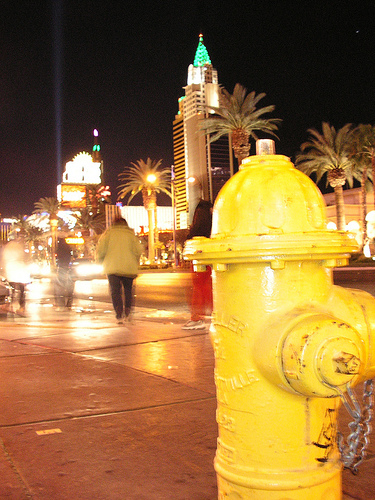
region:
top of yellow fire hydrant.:
[249, 180, 292, 219]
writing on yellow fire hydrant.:
[218, 369, 251, 456]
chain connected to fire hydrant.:
[345, 399, 366, 461]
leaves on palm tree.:
[220, 98, 273, 129]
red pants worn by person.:
[192, 282, 208, 315]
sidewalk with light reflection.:
[40, 318, 123, 396]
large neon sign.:
[68, 147, 101, 181]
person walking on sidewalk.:
[99, 216, 136, 309]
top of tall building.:
[189, 40, 213, 65]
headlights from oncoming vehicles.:
[78, 266, 101, 278]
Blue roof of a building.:
[168, 20, 223, 84]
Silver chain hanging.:
[314, 368, 373, 490]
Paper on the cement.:
[0, 371, 89, 478]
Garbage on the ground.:
[145, 348, 192, 399]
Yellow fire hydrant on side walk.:
[187, 155, 337, 493]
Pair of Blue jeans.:
[87, 272, 151, 353]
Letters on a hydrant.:
[190, 300, 247, 477]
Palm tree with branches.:
[113, 136, 193, 299]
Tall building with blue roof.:
[133, 15, 253, 263]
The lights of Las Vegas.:
[20, 111, 120, 218]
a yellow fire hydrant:
[182, 136, 362, 395]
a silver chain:
[323, 354, 370, 486]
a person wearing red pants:
[164, 183, 232, 325]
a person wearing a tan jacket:
[92, 216, 139, 289]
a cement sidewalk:
[0, 354, 212, 467]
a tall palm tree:
[114, 152, 180, 255]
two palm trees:
[294, 110, 372, 248]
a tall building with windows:
[163, 28, 238, 203]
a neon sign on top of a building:
[49, 150, 104, 207]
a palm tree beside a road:
[122, 81, 297, 307]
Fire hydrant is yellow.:
[177, 133, 373, 498]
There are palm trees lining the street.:
[9, 87, 373, 269]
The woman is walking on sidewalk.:
[82, 205, 157, 331]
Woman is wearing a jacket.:
[90, 222, 145, 280]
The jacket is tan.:
[85, 224, 150, 281]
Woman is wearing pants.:
[105, 274, 145, 323]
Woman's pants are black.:
[103, 272, 142, 327]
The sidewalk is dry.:
[2, 313, 231, 497]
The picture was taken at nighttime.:
[1, 0, 373, 220]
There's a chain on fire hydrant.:
[329, 371, 372, 478]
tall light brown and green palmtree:
[117, 159, 173, 260]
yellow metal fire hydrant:
[177, 138, 373, 499]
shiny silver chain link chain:
[335, 381, 373, 464]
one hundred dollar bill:
[35, 425, 63, 439]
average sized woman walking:
[94, 213, 148, 319]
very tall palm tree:
[196, 82, 273, 166]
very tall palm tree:
[290, 115, 363, 241]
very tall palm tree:
[346, 123, 371, 247]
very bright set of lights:
[62, 151, 101, 185]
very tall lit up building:
[167, 28, 242, 258]